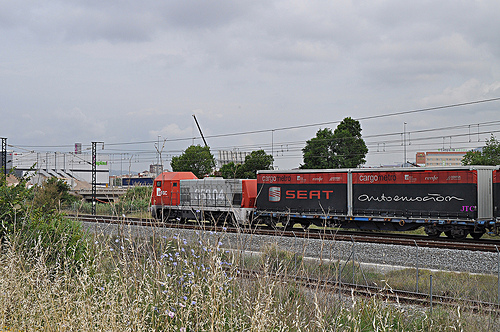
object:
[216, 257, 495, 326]
train rail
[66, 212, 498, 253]
train rail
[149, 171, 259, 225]
engine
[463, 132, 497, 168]
tree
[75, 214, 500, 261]
gravel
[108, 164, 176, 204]
building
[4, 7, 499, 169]
sky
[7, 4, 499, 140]
cloud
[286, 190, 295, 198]
red letters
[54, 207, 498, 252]
tracks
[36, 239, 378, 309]
grass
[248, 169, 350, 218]
cart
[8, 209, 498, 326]
ground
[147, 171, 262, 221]
engine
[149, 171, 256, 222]
car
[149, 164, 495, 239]
train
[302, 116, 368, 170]
tree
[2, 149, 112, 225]
structure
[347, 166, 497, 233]
car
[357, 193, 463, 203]
writing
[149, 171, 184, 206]
red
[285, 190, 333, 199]
sert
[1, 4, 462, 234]
background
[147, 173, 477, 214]
side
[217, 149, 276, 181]
tree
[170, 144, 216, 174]
tree